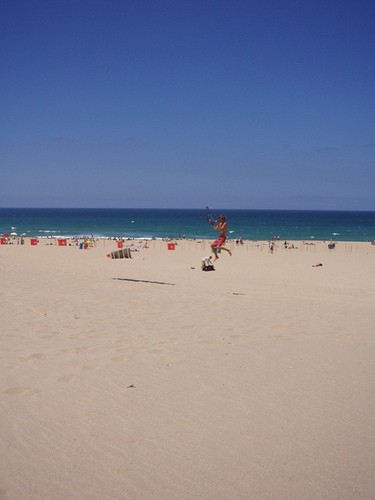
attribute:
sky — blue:
[159, 71, 235, 117]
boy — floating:
[210, 214, 236, 252]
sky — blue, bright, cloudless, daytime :
[1, 0, 374, 206]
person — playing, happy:
[204, 208, 237, 264]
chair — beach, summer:
[25, 234, 46, 252]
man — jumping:
[207, 209, 231, 259]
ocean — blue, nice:
[4, 188, 366, 247]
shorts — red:
[203, 216, 234, 262]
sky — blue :
[99, 48, 273, 155]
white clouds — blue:
[293, 117, 371, 169]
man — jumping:
[206, 210, 237, 264]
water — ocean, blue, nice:
[0, 207, 373, 240]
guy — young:
[208, 209, 238, 257]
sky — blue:
[71, 54, 351, 146]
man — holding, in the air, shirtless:
[207, 213, 231, 261]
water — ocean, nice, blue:
[8, 190, 373, 254]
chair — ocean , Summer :
[110, 245, 132, 258]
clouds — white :
[60, 125, 124, 150]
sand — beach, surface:
[3, 235, 374, 498]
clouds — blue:
[98, 97, 361, 187]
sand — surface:
[179, 242, 321, 350]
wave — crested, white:
[233, 223, 313, 240]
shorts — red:
[206, 238, 230, 261]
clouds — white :
[39, 37, 306, 156]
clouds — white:
[74, 85, 278, 142]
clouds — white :
[106, 106, 288, 168]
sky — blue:
[88, 66, 302, 140]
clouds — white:
[65, 53, 257, 112]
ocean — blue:
[2, 214, 374, 240]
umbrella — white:
[9, 231, 19, 237]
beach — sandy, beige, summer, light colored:
[0, 235, 372, 499]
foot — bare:
[228, 248, 233, 256]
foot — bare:
[213, 255, 218, 261]